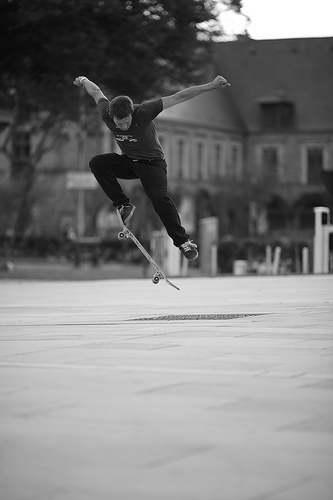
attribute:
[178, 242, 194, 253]
laces — white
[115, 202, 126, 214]
laces — white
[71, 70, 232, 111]
arm — extended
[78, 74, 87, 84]
band — white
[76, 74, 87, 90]
wrist — mans